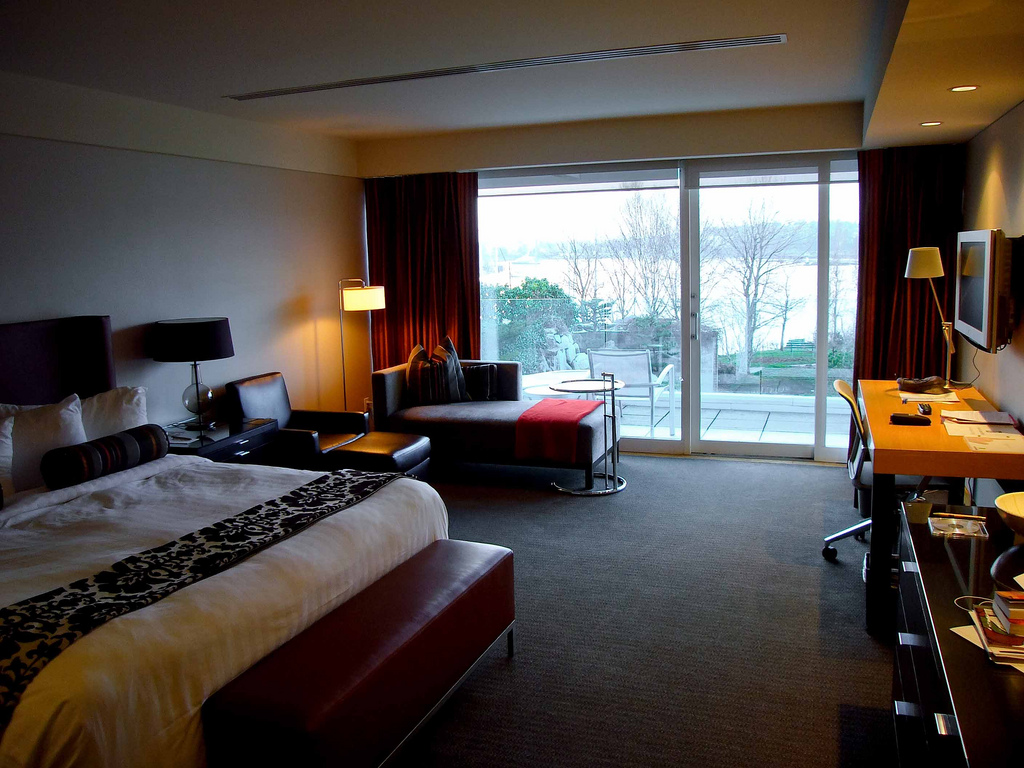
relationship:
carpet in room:
[450, 443, 854, 740] [33, 31, 943, 734]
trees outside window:
[506, 212, 844, 379] [370, 145, 939, 450]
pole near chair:
[359, 313, 388, 413] [218, 369, 366, 469]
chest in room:
[858, 481, 1018, 763] [9, 0, 1018, 763]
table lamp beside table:
[132, 300, 247, 404] [166, 427, 259, 464]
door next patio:
[683, 177, 831, 456] [594, 371, 850, 460]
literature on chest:
[925, 505, 1021, 668] [866, 490, 1022, 758]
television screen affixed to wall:
[922, 244, 989, 327] [948, 369, 996, 415]